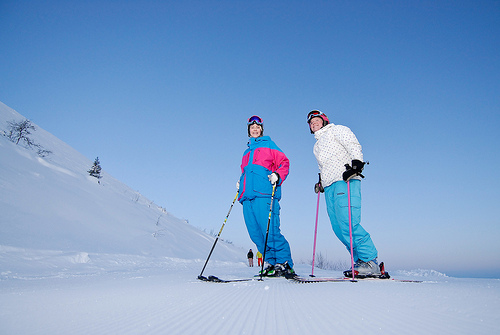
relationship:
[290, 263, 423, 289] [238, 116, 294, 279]
skis on female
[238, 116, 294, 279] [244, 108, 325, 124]
female with goggles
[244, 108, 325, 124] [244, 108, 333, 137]
goggles on heads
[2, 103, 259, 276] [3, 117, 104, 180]
hill with trees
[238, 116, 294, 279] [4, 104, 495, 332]
female on snow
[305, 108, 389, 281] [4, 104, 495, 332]
female skier on snow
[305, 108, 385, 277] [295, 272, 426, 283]
female skier on skis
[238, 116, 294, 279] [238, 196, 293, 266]
female wearing ski pants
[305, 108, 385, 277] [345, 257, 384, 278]
female skier wearing ski boots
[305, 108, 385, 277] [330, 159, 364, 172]
female skier wearing gloves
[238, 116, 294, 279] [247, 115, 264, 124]
female wearing goggles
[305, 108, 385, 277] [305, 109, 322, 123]
female skier wearing goggles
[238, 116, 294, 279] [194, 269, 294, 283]
female on skis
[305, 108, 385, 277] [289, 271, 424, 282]
female skier on skis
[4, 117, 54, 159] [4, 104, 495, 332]
brushes in snow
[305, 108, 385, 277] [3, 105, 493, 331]
female skier on ski slope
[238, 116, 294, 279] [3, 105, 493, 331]
female on ski slope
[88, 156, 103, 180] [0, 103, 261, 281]
pine tree on side of hill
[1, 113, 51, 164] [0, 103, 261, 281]
tree on side of hill